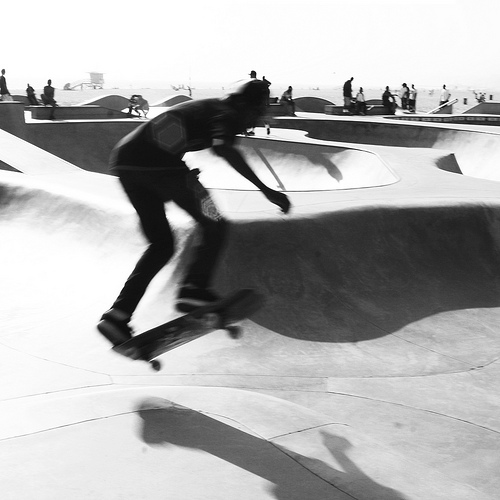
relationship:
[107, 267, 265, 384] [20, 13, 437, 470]
skateboard at skatepark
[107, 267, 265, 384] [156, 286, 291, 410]
skateboard in air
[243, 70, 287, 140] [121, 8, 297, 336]
hat on skateboarder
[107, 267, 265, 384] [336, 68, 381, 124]
skateboard with person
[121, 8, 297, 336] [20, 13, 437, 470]
skateboarder at skatepark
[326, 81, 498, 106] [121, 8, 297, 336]
skaters behind skateboarder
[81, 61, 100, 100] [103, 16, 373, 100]
hut on beach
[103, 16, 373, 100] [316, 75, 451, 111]
beach has people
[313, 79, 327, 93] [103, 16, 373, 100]
can on beach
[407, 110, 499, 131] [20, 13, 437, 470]
rail at skatepark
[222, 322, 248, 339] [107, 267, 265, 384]
wheel of skateboard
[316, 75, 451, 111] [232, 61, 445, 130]
people in distance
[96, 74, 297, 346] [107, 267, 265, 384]
skateboarder on skateboard